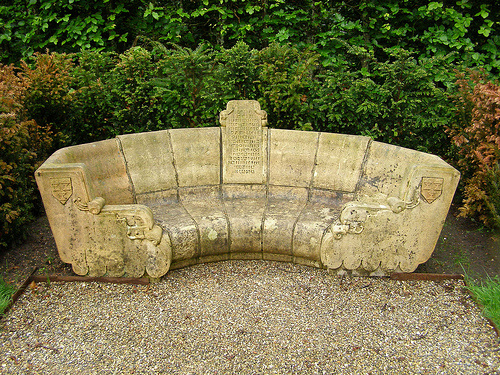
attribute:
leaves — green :
[347, 77, 388, 106]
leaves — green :
[367, 69, 418, 100]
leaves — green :
[408, 96, 456, 126]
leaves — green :
[327, 70, 391, 122]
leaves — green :
[168, 49, 217, 98]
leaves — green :
[428, 25, 476, 50]